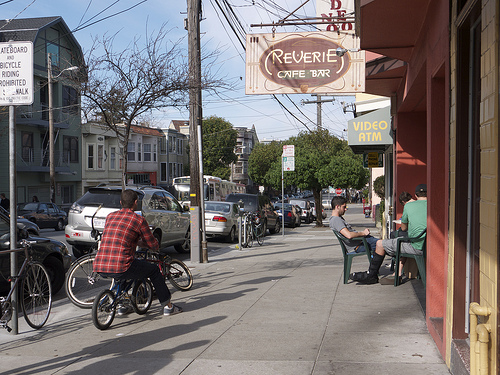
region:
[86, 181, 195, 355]
boy on bicycle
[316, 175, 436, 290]
guys sitting at cafe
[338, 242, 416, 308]
man has black cast on leg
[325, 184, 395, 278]
man sitting on green chair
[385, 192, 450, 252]
man wearing green shirt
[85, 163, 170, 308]
man wearing plaid shirt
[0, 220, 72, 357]
bicycle parked next to pole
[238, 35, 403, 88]
cafe bar sign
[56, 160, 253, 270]
silver car parked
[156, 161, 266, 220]
bus on the road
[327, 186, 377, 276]
man sitting on a green patio chair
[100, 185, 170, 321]
man riding a kid's bike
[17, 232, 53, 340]
a bicycle's wheel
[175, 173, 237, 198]
a bus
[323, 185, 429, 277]
three men sitting outside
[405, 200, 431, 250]
man wearing a green shirt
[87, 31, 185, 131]
a dead tree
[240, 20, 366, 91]
a coffee shop sign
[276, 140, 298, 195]
two parking signs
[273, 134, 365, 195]
green tree in full bloom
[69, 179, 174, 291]
man in a striped shirt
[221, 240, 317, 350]
gray sidewalk with cracks in it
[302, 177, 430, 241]
three men sitting around together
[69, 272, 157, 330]
small bike below the man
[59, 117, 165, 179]
houses to the left of the street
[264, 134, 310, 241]
sign above the street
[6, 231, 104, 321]
bikes parked next to each other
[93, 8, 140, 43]
blue sky above the land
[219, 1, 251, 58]
wires hanging off the poles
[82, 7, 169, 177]
dead tree on the sidewalk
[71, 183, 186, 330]
man on a mini bike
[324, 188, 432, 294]
three people sitting outside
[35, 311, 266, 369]
shadow of people on the sidewalk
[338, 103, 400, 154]
the words video atm in yellow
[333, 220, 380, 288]
a green plastic chair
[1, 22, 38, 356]
white sign stateing no skateboarding or bicycling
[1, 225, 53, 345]
a bike leaning on a pole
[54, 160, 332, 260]
street full of cars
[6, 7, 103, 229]
a four story building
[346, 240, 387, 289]
a black foot brace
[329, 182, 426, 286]
People sitting on green chairs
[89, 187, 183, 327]
Man riding a small bike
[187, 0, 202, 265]
Electric pole on the sidewalk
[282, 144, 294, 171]
Bus information on a stick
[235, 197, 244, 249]
Parking meter on the sidewalk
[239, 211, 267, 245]
Bike parked on the sidewalk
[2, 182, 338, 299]
Cars on the street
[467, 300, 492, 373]
Pipes stick to the wall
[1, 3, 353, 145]
Electric wires in the sky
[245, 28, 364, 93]
Sign hanging in front of a store